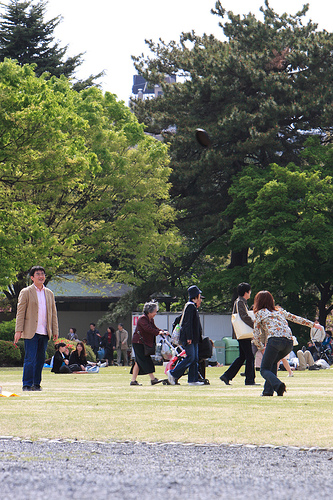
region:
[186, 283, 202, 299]
a blue hat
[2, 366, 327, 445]
a section of green grass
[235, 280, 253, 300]
a man's short cut black hair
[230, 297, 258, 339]
part of a large white bag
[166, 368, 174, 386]
a man's white shoe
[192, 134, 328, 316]
part of a large green tree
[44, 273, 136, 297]
part of a roof of a building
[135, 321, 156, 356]
part of a woman's black purse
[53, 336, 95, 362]
part of a large rose bush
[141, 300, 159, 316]
a woman's gray hair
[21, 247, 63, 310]
the head of a man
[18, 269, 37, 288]
the ear of a man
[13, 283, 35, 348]
the arm of a man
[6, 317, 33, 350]
the hand of a man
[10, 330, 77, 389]
the legs of a man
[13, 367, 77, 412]
the feet of a man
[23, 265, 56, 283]
the eyes of a man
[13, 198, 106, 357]
a man wearing a jacket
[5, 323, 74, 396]
a man wearing pants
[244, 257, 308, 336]
the head of a woman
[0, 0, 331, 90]
light in daytime sky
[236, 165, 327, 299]
green leaves on tree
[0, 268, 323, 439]
people on green grass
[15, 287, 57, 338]
tan coat on man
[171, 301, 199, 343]
bag strap on shoulder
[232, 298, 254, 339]
big white square bag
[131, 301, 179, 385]
woman pushing stroller handle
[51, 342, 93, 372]
people sitting on grass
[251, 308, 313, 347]
print on long sleeved shirt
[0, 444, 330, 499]
dirt surface in foreground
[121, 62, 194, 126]
Building behind the tree line.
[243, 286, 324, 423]
A woman rollerskating.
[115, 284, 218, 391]
Three adults walking a baby in a stroller.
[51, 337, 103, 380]
Two people sitting on the grass.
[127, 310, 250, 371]
A truck sitting by the field.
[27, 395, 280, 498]
Gravel path near the field.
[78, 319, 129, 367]
Three people walking by the field.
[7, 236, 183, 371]
A house behind the field.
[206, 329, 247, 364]
A few trash cans.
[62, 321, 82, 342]
A person looking at the house.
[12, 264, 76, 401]
a man standing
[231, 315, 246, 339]
person carrying a bag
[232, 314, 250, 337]
bag is white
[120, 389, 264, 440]
a field of grass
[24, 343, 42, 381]
man is wearing blue jeans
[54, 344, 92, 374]
people sitting on the grass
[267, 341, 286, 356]
women wearing jeans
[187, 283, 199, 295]
person wearing a hat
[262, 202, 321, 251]
the trees are green and tall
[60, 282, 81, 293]
the roof on the house